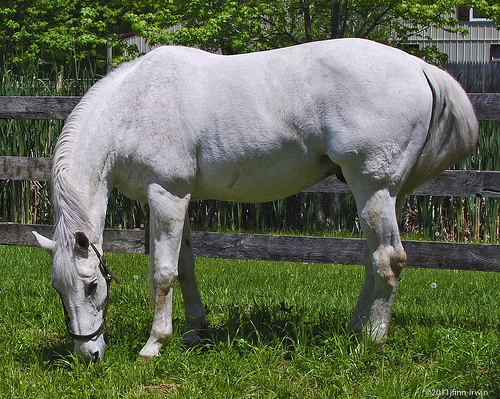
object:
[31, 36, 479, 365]
horse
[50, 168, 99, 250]
hair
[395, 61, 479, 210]
tail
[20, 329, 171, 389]
grass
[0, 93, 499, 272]
fence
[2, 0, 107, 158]
tree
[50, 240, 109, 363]
face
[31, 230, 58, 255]
ears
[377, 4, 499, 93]
building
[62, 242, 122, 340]
halter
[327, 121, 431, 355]
leg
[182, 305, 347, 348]
shadow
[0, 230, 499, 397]
ground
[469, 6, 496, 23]
window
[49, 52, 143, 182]
mane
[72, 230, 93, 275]
ear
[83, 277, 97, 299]
eye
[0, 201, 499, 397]
field